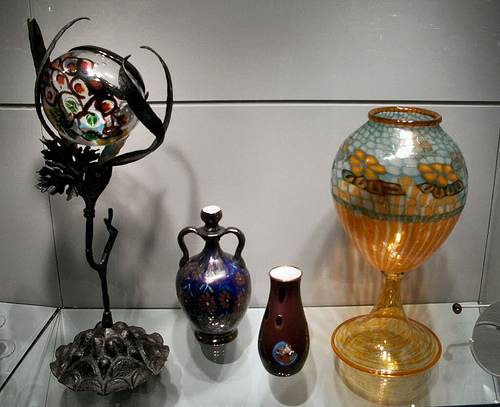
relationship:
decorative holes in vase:
[270, 290, 289, 330] [256, 263, 312, 378]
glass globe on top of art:
[25, 30, 182, 185] [39, 298, 188, 398]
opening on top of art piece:
[365, 95, 445, 130] [328, 103, 470, 379]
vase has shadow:
[256, 263, 312, 378] [262, 357, 321, 402]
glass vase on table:
[318, 90, 452, 377] [49, 305, 496, 389]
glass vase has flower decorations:
[329, 104, 471, 379] [348, 101, 462, 199]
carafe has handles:
[165, 200, 260, 351] [160, 219, 250, 270]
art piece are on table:
[25, 15, 175, 398] [0, 293, 490, 404]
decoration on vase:
[271, 340, 301, 370] [256, 263, 312, 378]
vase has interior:
[255, 263, 311, 377] [265, 263, 303, 284]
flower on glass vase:
[341, 140, 461, 192] [329, 104, 471, 379]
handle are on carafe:
[176, 225, 198, 269] [170, 195, 252, 341]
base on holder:
[46, 315, 172, 402] [16, 3, 176, 404]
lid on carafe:
[196, 199, 223, 219] [170, 202, 253, 348]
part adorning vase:
[268, 340, 301, 369] [255, 263, 311, 377]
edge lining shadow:
[266, 370, 286, 404] [268, 345, 318, 404]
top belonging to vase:
[267, 262, 303, 285] [255, 263, 311, 377]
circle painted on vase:
[270, 338, 297, 368] [255, 263, 311, 377]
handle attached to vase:
[175, 224, 202, 268] [173, 203, 252, 346]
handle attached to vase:
[223, 225, 248, 268] [173, 203, 252, 346]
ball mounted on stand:
[37, 47, 147, 147] [24, 14, 174, 396]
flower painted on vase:
[196, 290, 218, 315] [173, 203, 252, 346]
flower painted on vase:
[219, 291, 231, 309] [173, 203, 252, 346]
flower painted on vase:
[231, 265, 248, 287] [173, 203, 252, 346]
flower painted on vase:
[231, 290, 247, 318] [173, 203, 252, 346]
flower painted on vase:
[176, 290, 196, 310] [173, 203, 252, 346]